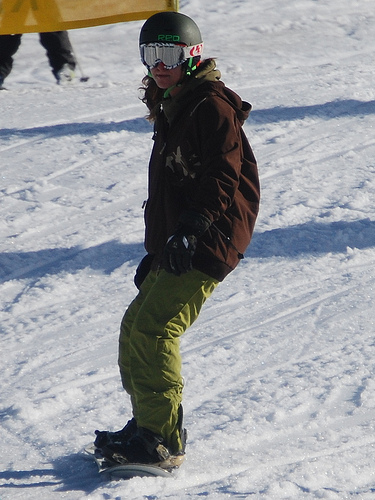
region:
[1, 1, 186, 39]
A yellow mesh sled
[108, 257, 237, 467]
Olive green snow pants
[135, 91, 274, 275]
A brown winter jacket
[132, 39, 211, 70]
Snow boarding goggles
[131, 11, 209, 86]
A black safety helmet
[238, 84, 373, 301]
Shadows in the snow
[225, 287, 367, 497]
Tracks in the snow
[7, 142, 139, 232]
The snow is white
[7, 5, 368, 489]
This picture was taken on a snowy hill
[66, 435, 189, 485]
A snow board in the snow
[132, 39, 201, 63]
Googles for snowboard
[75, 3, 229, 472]
Female snowboarding on the snow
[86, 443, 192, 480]
Small snowboard on the snow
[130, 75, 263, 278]
Brown snowboard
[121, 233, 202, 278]
Two black gloves for snowboard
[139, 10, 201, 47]
Black helmet on head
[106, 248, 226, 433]
Green impermeable pants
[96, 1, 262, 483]
Young female with long hair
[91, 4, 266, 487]
Woman snowboarding on the snow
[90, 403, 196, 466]
Boots for snowboard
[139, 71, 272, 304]
brown hooded ski jacket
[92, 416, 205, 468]
women's snow board bindings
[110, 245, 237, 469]
green snow pants with side zipper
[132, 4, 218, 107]
black helmet with green strap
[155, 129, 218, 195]
camo pocket on jacket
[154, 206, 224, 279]
black and white snow gloves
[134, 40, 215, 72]
ski goggles with white and red strap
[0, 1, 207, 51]
yellow sign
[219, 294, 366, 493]
sparkling packed white snow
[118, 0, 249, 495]
women snowboarder at end of hill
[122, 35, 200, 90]
goggles cover half of person's face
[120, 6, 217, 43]
black helmet has three green letters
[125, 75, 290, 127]
jacket hood is on the skateboarder's back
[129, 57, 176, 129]
long curly hair hanging down face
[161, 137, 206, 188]
different shapes decorate jacket front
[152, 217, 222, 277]
hand inside black and white glove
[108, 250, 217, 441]
wrinkled green pant with thick side seam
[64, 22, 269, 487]
snowboarding down an icy slope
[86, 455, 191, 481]
front rounded edge of snowboard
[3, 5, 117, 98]
legs behind wide tan banner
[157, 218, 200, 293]
black and sliver gloves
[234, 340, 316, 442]
snow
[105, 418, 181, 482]
a snow board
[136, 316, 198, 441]
green snow pants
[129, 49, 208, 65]
goggles on eyes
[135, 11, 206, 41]
a black and green helmet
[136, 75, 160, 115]
brown hair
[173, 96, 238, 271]
brown winter coat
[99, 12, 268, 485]
a person snowboarding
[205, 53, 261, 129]
two coats hoods